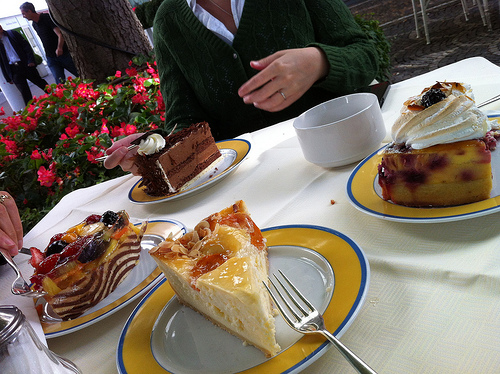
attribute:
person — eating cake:
[146, 0, 398, 137]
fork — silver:
[256, 261, 388, 373]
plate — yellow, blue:
[104, 216, 378, 374]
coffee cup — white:
[277, 85, 401, 179]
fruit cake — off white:
[364, 79, 499, 225]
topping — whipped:
[379, 75, 485, 145]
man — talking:
[13, 2, 79, 87]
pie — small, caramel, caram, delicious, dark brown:
[118, 123, 238, 193]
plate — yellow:
[124, 140, 256, 202]